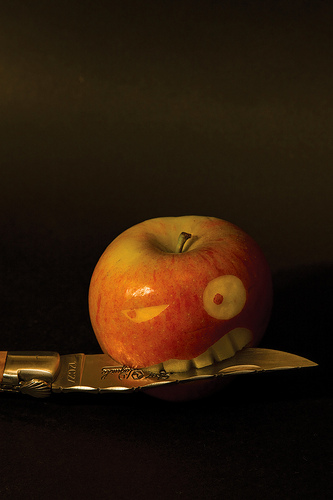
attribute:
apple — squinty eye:
[118, 298, 173, 324]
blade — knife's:
[83, 345, 318, 394]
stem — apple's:
[172, 227, 193, 254]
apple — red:
[58, 191, 283, 400]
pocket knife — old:
[1, 343, 318, 396]